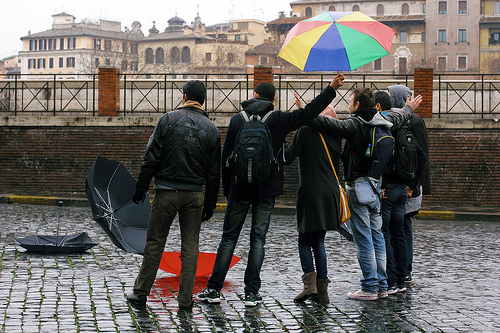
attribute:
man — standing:
[122, 80, 223, 310]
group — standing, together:
[122, 75, 434, 314]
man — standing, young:
[198, 73, 346, 312]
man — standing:
[293, 88, 392, 304]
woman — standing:
[284, 100, 346, 305]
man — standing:
[387, 82, 428, 285]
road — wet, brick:
[0, 203, 499, 332]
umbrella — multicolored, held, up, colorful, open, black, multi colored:
[274, 7, 399, 74]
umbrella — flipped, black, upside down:
[13, 198, 101, 257]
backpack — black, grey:
[226, 104, 278, 191]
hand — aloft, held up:
[326, 70, 348, 90]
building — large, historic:
[19, 11, 145, 82]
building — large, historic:
[136, 5, 211, 73]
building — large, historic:
[288, 0, 499, 79]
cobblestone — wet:
[73, 276, 90, 288]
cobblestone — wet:
[326, 307, 344, 318]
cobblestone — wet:
[3, 301, 25, 312]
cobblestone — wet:
[230, 319, 246, 328]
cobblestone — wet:
[57, 301, 76, 312]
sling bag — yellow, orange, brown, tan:
[317, 129, 352, 222]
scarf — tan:
[176, 99, 204, 112]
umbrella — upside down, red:
[152, 251, 242, 278]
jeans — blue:
[205, 180, 279, 297]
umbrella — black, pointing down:
[84, 152, 156, 258]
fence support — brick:
[97, 66, 122, 119]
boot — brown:
[291, 271, 319, 305]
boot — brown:
[309, 276, 333, 305]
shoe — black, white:
[242, 290, 263, 308]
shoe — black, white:
[195, 288, 223, 306]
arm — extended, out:
[384, 95, 424, 129]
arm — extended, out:
[291, 92, 355, 139]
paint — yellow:
[416, 209, 456, 221]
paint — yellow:
[214, 203, 229, 212]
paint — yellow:
[9, 194, 60, 206]